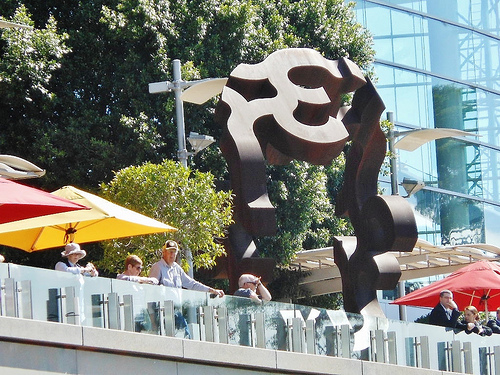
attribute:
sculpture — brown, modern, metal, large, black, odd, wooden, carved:
[184, 42, 417, 324]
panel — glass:
[110, 276, 209, 344]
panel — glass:
[9, 262, 115, 337]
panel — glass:
[208, 293, 295, 358]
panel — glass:
[294, 303, 380, 361]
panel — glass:
[378, 316, 454, 375]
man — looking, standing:
[430, 287, 477, 335]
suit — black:
[431, 302, 466, 333]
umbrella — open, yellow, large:
[0, 184, 178, 253]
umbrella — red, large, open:
[0, 172, 89, 225]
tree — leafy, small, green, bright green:
[94, 156, 237, 275]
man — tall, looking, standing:
[145, 239, 225, 299]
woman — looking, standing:
[116, 254, 162, 286]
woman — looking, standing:
[53, 239, 97, 280]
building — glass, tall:
[340, 1, 499, 331]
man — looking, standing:
[232, 273, 274, 305]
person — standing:
[460, 303, 492, 336]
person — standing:
[487, 302, 500, 331]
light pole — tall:
[169, 57, 194, 177]